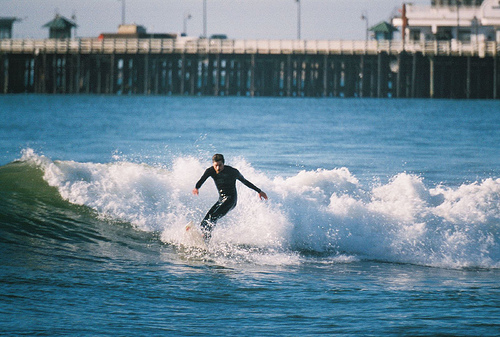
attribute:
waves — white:
[158, 281, 269, 324]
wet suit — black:
[177, 147, 274, 267]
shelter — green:
[37, 51, 81, 73]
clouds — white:
[98, 53, 119, 66]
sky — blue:
[285, 99, 299, 106]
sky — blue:
[36, 51, 70, 63]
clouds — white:
[1, 99, 141, 104]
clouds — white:
[98, 52, 157, 61]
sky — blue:
[272, 99, 370, 115]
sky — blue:
[63, 51, 101, 73]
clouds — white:
[33, 106, 207, 116]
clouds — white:
[35, 51, 67, 54]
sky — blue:
[354, 99, 465, 143]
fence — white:
[47, 105, 497, 133]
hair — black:
[212, 154, 222, 164]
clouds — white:
[28, 65, 94, 93]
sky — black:
[352, 111, 459, 162]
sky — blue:
[34, 72, 91, 105]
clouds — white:
[40, 100, 80, 119]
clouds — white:
[12, 64, 152, 84]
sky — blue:
[73, 101, 145, 141]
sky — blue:
[1, 0, 439, 37]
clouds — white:
[1, 0, 429, 43]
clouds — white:
[2, 0, 404, 38]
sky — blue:
[0, 0, 402, 40]